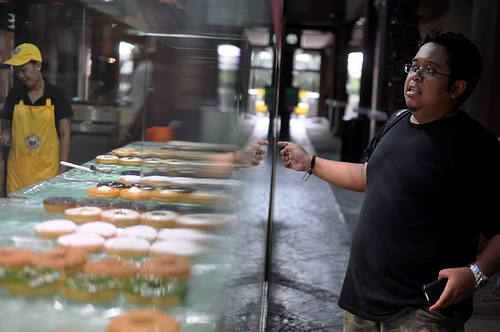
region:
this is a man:
[334, 25, 484, 327]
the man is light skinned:
[326, 162, 351, 187]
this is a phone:
[425, 276, 440, 300]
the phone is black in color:
[427, 273, 444, 296]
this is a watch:
[465, 254, 498, 294]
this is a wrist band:
[304, 148, 325, 184]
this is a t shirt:
[381, 160, 448, 272]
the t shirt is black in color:
[408, 126, 443, 194]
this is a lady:
[8, 39, 65, 163]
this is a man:
[290, 25, 437, 329]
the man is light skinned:
[326, 155, 352, 184]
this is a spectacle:
[399, 61, 441, 77]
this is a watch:
[465, 259, 495, 283]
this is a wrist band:
[300, 141, 321, 179]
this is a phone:
[418, 270, 445, 292]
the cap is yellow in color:
[11, 46, 42, 53]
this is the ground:
[294, 185, 334, 264]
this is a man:
[316, 32, 490, 305]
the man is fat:
[334, 27, 481, 322]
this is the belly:
[350, 192, 424, 275]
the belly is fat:
[343, 170, 430, 284]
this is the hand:
[275, 142, 375, 192]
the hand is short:
[279, 132, 372, 188]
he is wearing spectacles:
[400, 60, 437, 77]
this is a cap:
[7, 42, 39, 63]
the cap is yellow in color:
[4, 42, 38, 67]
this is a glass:
[174, 170, 271, 273]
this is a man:
[323, 35, 487, 313]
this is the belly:
[357, 182, 419, 253]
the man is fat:
[329, 42, 481, 307]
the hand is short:
[282, 144, 372, 191]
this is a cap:
[2, 37, 42, 67]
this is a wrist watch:
[470, 257, 493, 289]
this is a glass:
[222, 142, 270, 228]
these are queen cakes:
[40, 209, 185, 284]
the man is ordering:
[268, 31, 498, 288]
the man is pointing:
[291, 31, 486, 321]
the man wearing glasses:
[396, 56, 453, 90]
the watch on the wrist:
[462, 255, 496, 295]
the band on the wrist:
[297, 149, 323, 180]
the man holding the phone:
[403, 261, 475, 318]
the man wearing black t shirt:
[362, 106, 489, 312]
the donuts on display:
[37, 111, 259, 330]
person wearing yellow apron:
[3, 93, 80, 182]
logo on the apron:
[19, 133, 44, 154]